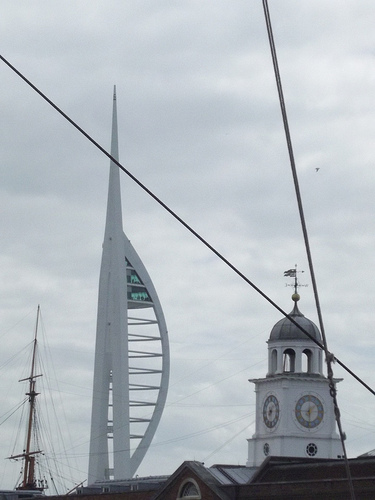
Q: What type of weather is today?
A: It is cloudy.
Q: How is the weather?
A: It is cloudy.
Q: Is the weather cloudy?
A: Yes, it is cloudy.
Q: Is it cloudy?
A: Yes, it is cloudy.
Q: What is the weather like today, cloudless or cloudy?
A: It is cloudy.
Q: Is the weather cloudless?
A: No, it is cloudy.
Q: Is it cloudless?
A: No, it is cloudy.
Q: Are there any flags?
A: No, there are no flags.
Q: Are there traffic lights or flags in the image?
A: No, there are no flags or traffic lights.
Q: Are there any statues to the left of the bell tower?
A: Yes, there is a statue to the left of the bell tower.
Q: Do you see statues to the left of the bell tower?
A: Yes, there is a statue to the left of the bell tower.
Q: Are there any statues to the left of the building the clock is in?
A: Yes, there is a statue to the left of the bell tower.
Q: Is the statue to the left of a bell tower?
A: Yes, the statue is to the left of a bell tower.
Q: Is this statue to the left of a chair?
A: No, the statue is to the left of a bell tower.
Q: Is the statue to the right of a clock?
A: No, the statue is to the left of a clock.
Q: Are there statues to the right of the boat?
A: Yes, there is a statue to the right of the boat.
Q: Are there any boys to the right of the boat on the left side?
A: No, there is a statue to the right of the boat.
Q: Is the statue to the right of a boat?
A: Yes, the statue is to the right of a boat.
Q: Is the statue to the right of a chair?
A: No, the statue is to the right of a boat.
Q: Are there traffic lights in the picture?
A: No, there are no traffic lights.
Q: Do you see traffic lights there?
A: No, there are no traffic lights.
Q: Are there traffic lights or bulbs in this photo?
A: No, there are no traffic lights or bulbs.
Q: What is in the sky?
A: The wires are in the sky.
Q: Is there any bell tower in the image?
A: Yes, there is a bell tower.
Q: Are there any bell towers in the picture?
A: Yes, there is a bell tower.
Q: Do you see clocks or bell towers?
A: Yes, there is a bell tower.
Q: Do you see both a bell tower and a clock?
A: Yes, there are both a bell tower and a clock.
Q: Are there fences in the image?
A: No, there are no fences.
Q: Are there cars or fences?
A: No, there are no fences or cars.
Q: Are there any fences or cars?
A: No, there are no fences or cars.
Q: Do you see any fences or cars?
A: No, there are no fences or cars.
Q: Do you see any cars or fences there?
A: No, there are no fences or cars.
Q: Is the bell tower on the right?
A: Yes, the bell tower is on the right of the image.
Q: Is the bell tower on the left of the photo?
A: No, the bell tower is on the right of the image.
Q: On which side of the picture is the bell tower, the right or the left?
A: The bell tower is on the right of the image.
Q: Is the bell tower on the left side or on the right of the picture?
A: The bell tower is on the right of the image.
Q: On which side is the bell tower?
A: The bell tower is on the right of the image.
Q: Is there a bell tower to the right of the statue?
A: Yes, there is a bell tower to the right of the statue.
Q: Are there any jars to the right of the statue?
A: No, there is a bell tower to the right of the statue.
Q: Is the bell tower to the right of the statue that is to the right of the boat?
A: Yes, the bell tower is to the right of the statue.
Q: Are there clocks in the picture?
A: Yes, there is a clock.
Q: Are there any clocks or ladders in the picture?
A: Yes, there is a clock.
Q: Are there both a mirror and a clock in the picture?
A: No, there is a clock but no mirrors.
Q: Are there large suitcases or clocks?
A: Yes, there is a large clock.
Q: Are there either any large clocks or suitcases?
A: Yes, there is a large clock.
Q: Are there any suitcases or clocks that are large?
A: Yes, the clock is large.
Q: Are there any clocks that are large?
A: Yes, there is a large clock.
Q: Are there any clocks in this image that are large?
A: Yes, there is a clock that is large.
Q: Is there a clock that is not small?
A: Yes, there is a large clock.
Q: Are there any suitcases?
A: No, there are no suitcases.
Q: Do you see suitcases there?
A: No, there are no suitcases.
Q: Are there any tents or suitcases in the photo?
A: No, there are no suitcases or tents.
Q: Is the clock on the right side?
A: Yes, the clock is on the right of the image.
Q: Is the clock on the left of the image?
A: No, the clock is on the right of the image.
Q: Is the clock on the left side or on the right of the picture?
A: The clock is on the right of the image.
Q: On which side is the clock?
A: The clock is on the right of the image.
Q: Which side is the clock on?
A: The clock is on the right of the image.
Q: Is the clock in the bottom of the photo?
A: Yes, the clock is in the bottom of the image.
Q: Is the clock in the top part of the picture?
A: No, the clock is in the bottom of the image.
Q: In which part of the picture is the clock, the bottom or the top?
A: The clock is in the bottom of the image.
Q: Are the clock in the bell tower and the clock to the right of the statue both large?
A: Yes, both the clock and the clock are large.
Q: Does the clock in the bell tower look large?
A: Yes, the clock is large.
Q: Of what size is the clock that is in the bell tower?
A: The clock is large.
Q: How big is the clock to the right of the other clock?
A: The clock is large.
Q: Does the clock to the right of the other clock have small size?
A: No, the clock is large.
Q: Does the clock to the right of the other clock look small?
A: No, the clock is large.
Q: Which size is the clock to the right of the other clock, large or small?
A: The clock is large.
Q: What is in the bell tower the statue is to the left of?
A: The clock is in the bell tower.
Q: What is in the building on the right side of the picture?
A: The clock is in the bell tower.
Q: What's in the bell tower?
A: The clock is in the bell tower.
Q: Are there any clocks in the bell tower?
A: Yes, there is a clock in the bell tower.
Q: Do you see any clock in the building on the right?
A: Yes, there is a clock in the bell tower.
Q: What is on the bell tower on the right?
A: The clock is on the bell tower.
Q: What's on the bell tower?
A: The clock is on the bell tower.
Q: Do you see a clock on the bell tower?
A: Yes, there is a clock on the bell tower.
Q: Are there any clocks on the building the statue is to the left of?
A: Yes, there is a clock on the bell tower.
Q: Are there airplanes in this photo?
A: No, there are no airplanes.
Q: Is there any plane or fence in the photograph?
A: No, there are no airplanes or fences.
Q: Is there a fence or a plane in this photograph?
A: No, there are no airplanes or fences.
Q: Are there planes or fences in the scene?
A: No, there are no planes or fences.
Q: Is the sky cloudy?
A: Yes, the sky is cloudy.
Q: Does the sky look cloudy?
A: Yes, the sky is cloudy.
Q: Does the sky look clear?
A: No, the sky is cloudy.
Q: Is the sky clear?
A: No, the sky is cloudy.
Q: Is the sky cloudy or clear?
A: The sky is cloudy.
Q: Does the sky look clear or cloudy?
A: The sky is cloudy.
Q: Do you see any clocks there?
A: Yes, there is a clock.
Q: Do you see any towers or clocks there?
A: Yes, there is a clock.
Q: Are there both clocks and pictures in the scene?
A: No, there is a clock but no pictures.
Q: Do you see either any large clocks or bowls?
A: Yes, there is a large clock.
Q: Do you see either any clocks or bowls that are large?
A: Yes, the clock is large.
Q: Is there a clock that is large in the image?
A: Yes, there is a large clock.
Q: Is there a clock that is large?
A: Yes, there is a clock that is large.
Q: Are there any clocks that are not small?
A: Yes, there is a large clock.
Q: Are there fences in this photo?
A: No, there are no fences.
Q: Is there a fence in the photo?
A: No, there are no fences.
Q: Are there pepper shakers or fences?
A: No, there are no fences or pepper shakers.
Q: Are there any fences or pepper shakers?
A: No, there are no fences or pepper shakers.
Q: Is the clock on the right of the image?
A: Yes, the clock is on the right of the image.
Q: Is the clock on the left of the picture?
A: No, the clock is on the right of the image.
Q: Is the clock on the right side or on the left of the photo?
A: The clock is on the right of the image.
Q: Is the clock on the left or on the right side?
A: The clock is on the right of the image.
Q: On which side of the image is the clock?
A: The clock is on the right of the image.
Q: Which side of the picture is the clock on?
A: The clock is on the right of the image.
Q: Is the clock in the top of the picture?
A: No, the clock is in the bottom of the image.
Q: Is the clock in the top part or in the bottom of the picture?
A: The clock is in the bottom of the image.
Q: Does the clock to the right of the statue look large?
A: Yes, the clock is large.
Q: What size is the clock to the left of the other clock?
A: The clock is large.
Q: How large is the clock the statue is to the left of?
A: The clock is large.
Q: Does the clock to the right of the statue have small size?
A: No, the clock is large.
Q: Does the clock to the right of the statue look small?
A: No, the clock is large.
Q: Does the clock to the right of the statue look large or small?
A: The clock is large.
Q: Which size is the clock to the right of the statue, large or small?
A: The clock is large.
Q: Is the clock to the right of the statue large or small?
A: The clock is large.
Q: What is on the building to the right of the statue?
A: The clock is on the bell tower.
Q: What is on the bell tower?
A: The clock is on the bell tower.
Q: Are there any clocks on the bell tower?
A: Yes, there is a clock on the bell tower.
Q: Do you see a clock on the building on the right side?
A: Yes, there is a clock on the bell tower.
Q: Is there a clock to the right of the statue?
A: Yes, there is a clock to the right of the statue.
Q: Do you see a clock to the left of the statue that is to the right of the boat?
A: No, the clock is to the right of the statue.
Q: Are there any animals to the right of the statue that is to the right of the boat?
A: No, there is a clock to the right of the statue.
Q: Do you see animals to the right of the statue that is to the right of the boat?
A: No, there is a clock to the right of the statue.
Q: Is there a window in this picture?
A: Yes, there is a window.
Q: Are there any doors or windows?
A: Yes, there is a window.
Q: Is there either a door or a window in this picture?
A: Yes, there is a window.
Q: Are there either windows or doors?
A: Yes, there is a window.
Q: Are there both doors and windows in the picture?
A: No, there is a window but no doors.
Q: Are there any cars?
A: No, there are no cars.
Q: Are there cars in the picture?
A: No, there are no cars.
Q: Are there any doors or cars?
A: No, there are no cars or doors.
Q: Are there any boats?
A: Yes, there is a boat.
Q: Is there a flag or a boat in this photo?
A: Yes, there is a boat.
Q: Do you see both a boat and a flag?
A: No, there is a boat but no flags.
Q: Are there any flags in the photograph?
A: No, there are no flags.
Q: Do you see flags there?
A: No, there are no flags.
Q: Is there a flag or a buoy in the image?
A: No, there are no flags or buoys.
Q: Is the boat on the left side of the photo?
A: Yes, the boat is on the left of the image.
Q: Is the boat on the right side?
A: No, the boat is on the left of the image.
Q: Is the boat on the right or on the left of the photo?
A: The boat is on the left of the image.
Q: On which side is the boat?
A: The boat is on the left of the image.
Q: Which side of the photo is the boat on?
A: The boat is on the left of the image.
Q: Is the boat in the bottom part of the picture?
A: Yes, the boat is in the bottom of the image.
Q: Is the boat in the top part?
A: No, the boat is in the bottom of the image.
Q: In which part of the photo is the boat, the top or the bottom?
A: The boat is in the bottom of the image.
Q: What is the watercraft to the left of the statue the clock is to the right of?
A: The watercraft is a boat.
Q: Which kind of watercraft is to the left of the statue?
A: The watercraft is a boat.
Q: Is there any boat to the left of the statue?
A: Yes, there is a boat to the left of the statue.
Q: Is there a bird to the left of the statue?
A: No, there is a boat to the left of the statue.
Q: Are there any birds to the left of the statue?
A: No, there is a boat to the left of the statue.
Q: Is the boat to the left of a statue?
A: Yes, the boat is to the left of a statue.